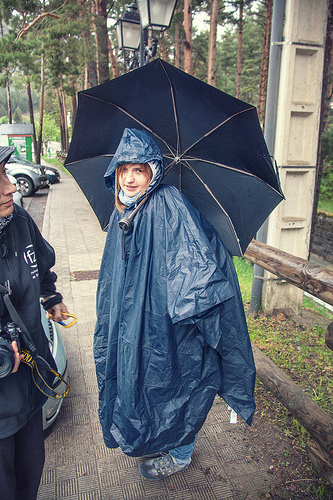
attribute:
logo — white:
[20, 243, 51, 291]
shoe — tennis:
[134, 453, 193, 481]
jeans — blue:
[169, 433, 198, 459]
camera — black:
[0, 336, 40, 380]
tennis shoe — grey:
[138, 456, 193, 478]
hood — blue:
[101, 124, 167, 210]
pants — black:
[0, 409, 53, 495]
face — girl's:
[108, 145, 151, 186]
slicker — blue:
[93, 128, 256, 445]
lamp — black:
[111, 4, 152, 53]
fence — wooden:
[244, 240, 332, 306]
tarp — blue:
[95, 128, 260, 449]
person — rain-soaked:
[92, 128, 255, 480]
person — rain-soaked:
[1, 146, 68, 499]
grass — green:
[232, 255, 256, 303]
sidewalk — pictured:
[33, 155, 295, 499]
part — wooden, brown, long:
[276, 377, 293, 405]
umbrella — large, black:
[62, 57, 284, 261]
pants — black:
[0, 407, 44, 498]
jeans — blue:
[137, 433, 198, 479]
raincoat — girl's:
[37, 96, 288, 466]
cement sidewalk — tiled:
[58, 187, 102, 302]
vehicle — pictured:
[6, 156, 48, 197]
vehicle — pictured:
[14, 155, 61, 184]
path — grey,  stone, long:
[27, 110, 135, 297]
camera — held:
[0, 288, 77, 408]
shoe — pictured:
[149, 456, 184, 465]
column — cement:
[260, 30, 321, 307]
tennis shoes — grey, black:
[143, 441, 194, 482]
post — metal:
[248, 0, 285, 317]